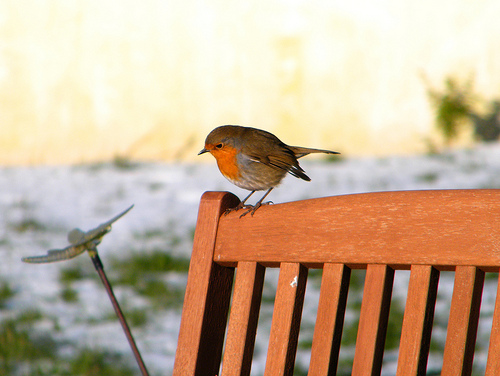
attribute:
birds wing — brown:
[242, 123, 312, 188]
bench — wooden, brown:
[173, 187, 498, 373]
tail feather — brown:
[289, 142, 344, 160]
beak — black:
[191, 148, 210, 162]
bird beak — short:
[194, 148, 214, 154]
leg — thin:
[252, 182, 276, 204]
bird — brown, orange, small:
[196, 121, 341, 217]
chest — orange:
[210, 146, 237, 178]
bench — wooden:
[168, 163, 483, 331]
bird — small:
[189, 122, 333, 214]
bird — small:
[181, 103, 344, 230]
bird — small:
[196, 128, 331, 213]